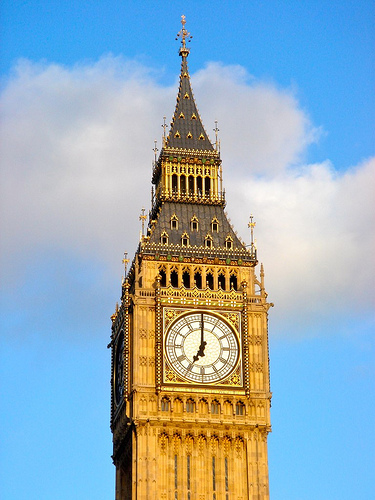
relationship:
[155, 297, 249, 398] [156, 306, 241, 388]
clock clock white clock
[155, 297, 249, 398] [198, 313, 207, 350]
clock has black hands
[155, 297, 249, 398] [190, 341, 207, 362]
clock has hand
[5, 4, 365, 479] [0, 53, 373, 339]
blue sky has cloud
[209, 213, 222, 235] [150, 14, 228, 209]
window on pointed roof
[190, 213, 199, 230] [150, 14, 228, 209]
window on pointed roof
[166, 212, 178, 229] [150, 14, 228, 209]
window on pointed roof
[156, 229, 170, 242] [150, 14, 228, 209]
window on pointed roof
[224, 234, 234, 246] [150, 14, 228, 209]
window on pointed roof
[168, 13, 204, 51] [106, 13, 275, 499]
cross on top of building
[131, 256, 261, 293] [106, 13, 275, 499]
cornice design on building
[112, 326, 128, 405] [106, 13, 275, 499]
clock on side of building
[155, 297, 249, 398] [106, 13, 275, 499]
clock on side of building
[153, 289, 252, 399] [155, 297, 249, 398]
elegant frame around clock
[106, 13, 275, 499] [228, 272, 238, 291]
building has doorway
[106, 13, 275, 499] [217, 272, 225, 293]
building has doorway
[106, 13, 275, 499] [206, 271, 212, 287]
building has doorway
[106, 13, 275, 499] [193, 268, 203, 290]
building has doorway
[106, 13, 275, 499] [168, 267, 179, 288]
building has doorway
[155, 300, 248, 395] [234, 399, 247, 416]
clock has arch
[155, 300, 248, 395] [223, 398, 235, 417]
clock has arch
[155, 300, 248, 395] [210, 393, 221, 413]
clock has arch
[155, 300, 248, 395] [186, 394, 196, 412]
clock has arch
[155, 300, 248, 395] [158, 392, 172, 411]
clock has arch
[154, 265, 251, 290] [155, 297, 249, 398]
open arches above clock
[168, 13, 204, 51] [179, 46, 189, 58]
cross on ball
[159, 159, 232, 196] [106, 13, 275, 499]
parapets on building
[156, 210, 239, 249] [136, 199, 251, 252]
windows on roof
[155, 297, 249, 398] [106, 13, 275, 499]
clock on building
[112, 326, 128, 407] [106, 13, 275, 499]
clock on building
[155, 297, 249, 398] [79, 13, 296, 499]
clock on building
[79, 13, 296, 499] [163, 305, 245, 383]
building with clock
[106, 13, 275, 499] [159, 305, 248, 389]
building with clock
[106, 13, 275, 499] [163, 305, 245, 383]
building with clock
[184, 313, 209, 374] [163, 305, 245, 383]
black hands on a clock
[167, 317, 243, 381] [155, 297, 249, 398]
roman numerals on a clock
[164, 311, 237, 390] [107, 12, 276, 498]
clock face in a clock tower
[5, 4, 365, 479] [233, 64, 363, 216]
blue sky above clouds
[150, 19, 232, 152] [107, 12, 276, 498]
pointed roof on clock tower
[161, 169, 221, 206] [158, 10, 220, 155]
arched openings under pointed roof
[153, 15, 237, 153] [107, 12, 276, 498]
spire on a clock tower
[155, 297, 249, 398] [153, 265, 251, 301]
clock has a gate